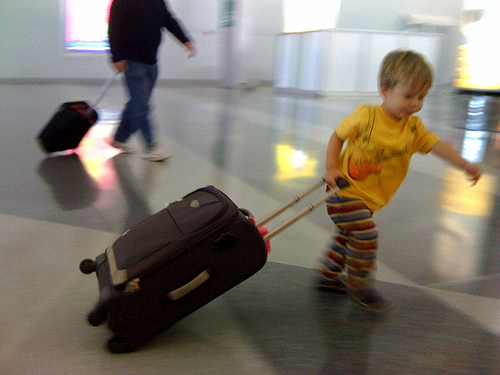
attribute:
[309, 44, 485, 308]
child — little, dirty blonde, male, small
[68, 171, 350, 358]
suitcase — black, canvas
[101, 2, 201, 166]
adult — walking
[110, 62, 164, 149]
jeans — blue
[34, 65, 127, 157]
suitcase — black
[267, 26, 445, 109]
counters — white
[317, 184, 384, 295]
pants — striped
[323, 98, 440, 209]
top — yellow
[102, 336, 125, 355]
wheel — black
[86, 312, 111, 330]
wheel — black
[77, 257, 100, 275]
wheel — black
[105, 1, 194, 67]
top — dark, black, pull on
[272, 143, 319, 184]
area — yellow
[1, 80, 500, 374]
floor — grey, white, granite, waxed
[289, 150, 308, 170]
circle — white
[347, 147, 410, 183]
guitar — red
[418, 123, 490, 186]
left arm — extended